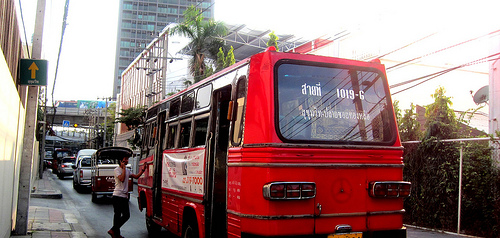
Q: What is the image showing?
A: It is showing a road.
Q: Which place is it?
A: It is a road.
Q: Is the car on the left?
A: Yes, the car is on the left of the image.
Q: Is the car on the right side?
A: No, the car is on the left of the image.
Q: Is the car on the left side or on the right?
A: The car is on the left of the image.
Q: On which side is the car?
A: The car is on the left of the image.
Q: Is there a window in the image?
A: Yes, there is a window.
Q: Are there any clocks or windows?
A: Yes, there is a window.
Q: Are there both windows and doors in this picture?
A: Yes, there are both a window and doors.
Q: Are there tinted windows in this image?
A: Yes, there is a tinted window.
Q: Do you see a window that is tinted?
A: Yes, there is a window that is tinted.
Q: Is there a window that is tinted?
A: Yes, there is a window that is tinted.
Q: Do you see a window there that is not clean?
A: Yes, there is a tinted window.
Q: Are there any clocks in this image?
A: No, there are no clocks.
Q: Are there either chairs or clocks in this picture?
A: No, there are no clocks or chairs.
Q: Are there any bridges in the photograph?
A: Yes, there is a bridge.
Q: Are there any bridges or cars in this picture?
A: Yes, there is a bridge.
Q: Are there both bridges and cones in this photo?
A: No, there is a bridge but no cones.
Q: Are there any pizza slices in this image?
A: No, there are no pizza slices.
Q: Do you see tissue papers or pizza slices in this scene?
A: No, there are no pizza slices or tissue papers.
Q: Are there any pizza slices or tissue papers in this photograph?
A: No, there are no pizza slices or tissue papers.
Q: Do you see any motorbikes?
A: No, there are no motorbikes.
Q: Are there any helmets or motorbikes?
A: No, there are no motorbikes or helmets.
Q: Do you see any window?
A: Yes, there is a window.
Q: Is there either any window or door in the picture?
A: Yes, there is a window.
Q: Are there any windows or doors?
A: Yes, there is a window.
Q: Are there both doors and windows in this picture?
A: Yes, there are both a window and a door.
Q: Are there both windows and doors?
A: Yes, there are both a window and a door.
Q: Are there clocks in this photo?
A: No, there are no clocks.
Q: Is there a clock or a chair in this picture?
A: No, there are no clocks or chairs.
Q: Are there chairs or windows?
A: Yes, there is a window.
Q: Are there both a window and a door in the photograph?
A: Yes, there are both a window and a door.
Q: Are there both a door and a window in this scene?
A: Yes, there are both a window and a door.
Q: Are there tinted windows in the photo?
A: Yes, there is a tinted window.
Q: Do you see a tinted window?
A: Yes, there is a tinted window.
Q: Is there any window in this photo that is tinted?
A: Yes, there is a window that is tinted.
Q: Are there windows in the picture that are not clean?
A: Yes, there is a tinted window.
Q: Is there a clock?
A: No, there are no clocks.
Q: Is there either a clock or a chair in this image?
A: No, there are no clocks or chairs.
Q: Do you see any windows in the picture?
A: Yes, there is a window.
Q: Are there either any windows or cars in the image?
A: Yes, there is a window.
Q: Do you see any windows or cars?
A: Yes, there is a window.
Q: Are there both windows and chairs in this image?
A: No, there is a window but no chairs.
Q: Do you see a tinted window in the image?
A: Yes, there is a tinted window.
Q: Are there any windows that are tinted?
A: Yes, there is a window that is tinted.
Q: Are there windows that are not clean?
A: Yes, there is a tinted window.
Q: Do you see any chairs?
A: No, there are no chairs.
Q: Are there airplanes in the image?
A: No, there are no airplanes.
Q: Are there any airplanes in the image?
A: No, there are no airplanes.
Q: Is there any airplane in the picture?
A: No, there are no airplanes.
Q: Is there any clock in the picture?
A: No, there are no clocks.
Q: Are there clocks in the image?
A: No, there are no clocks.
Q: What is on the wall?
A: The sign is on the wall.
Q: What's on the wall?
A: The sign is on the wall.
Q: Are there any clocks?
A: No, there are no clocks.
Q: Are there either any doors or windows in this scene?
A: Yes, there is a window.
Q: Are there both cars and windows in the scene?
A: Yes, there are both a window and a car.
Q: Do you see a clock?
A: No, there are no clocks.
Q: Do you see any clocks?
A: No, there are no clocks.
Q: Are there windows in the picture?
A: Yes, there is a window.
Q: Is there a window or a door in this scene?
A: Yes, there is a window.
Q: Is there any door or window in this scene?
A: Yes, there is a window.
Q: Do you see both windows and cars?
A: Yes, there are both a window and a car.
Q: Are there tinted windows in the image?
A: Yes, there is a tinted window.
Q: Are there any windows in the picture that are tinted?
A: Yes, there is a window that is tinted.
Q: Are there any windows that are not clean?
A: Yes, there is a tinted window.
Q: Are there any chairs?
A: No, there are no chairs.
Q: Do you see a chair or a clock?
A: No, there are no chairs or clocks.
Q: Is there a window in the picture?
A: Yes, there is a window.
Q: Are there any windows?
A: Yes, there is a window.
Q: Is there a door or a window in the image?
A: Yes, there is a window.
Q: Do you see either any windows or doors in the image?
A: Yes, there is a window.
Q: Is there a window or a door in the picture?
A: Yes, there is a window.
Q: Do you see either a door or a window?
A: Yes, there is a window.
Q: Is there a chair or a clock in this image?
A: No, there are no clocks or chairs.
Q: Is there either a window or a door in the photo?
A: Yes, there is a window.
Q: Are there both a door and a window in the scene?
A: Yes, there are both a window and a door.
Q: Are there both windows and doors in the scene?
A: Yes, there are both a window and a door.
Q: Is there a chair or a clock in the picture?
A: No, there are no clocks or chairs.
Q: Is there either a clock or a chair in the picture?
A: No, there are no clocks or chairs.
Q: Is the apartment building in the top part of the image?
A: Yes, the apartment building is in the top of the image.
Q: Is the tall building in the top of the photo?
A: Yes, the apartment building is in the top of the image.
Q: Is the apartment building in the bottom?
A: No, the apartment building is in the top of the image.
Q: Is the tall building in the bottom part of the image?
A: No, the apartment building is in the top of the image.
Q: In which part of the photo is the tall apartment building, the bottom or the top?
A: The apartment building is in the top of the image.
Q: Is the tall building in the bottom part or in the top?
A: The apartment building is in the top of the image.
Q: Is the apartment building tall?
A: Yes, the apartment building is tall.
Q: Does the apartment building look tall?
A: Yes, the apartment building is tall.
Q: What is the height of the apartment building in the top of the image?
A: The apartment building is tall.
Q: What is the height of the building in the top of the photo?
A: The apartment building is tall.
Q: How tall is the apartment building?
A: The apartment building is tall.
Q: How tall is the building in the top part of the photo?
A: The apartment building is tall.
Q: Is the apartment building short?
A: No, the apartment building is tall.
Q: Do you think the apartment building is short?
A: No, the apartment building is tall.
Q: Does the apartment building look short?
A: No, the apartment building is tall.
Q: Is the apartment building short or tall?
A: The apartment building is tall.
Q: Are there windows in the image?
A: Yes, there is a window.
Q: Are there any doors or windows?
A: Yes, there is a window.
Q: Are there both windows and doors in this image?
A: Yes, there are both a window and doors.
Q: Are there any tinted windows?
A: Yes, there is a tinted window.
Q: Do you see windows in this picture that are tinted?
A: Yes, there is a window that is tinted.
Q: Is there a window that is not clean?
A: Yes, there is a tinted window.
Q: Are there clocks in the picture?
A: No, there are no clocks.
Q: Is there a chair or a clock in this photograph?
A: No, there are no clocks or chairs.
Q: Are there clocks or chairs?
A: No, there are no clocks or chairs.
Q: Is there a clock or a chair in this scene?
A: No, there are no clocks or chairs.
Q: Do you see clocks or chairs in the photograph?
A: No, there are no clocks or chairs.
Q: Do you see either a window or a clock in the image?
A: Yes, there is a window.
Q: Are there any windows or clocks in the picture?
A: Yes, there is a window.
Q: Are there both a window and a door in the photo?
A: Yes, there are both a window and a door.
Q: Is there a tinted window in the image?
A: Yes, there is a tinted window.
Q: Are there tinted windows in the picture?
A: Yes, there is a tinted window.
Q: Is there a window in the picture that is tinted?
A: Yes, there is a window that is tinted.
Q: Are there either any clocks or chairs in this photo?
A: No, there are no clocks or chairs.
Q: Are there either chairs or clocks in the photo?
A: No, there are no clocks or chairs.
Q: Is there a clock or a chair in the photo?
A: No, there are no clocks or chairs.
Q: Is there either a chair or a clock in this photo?
A: No, there are no clocks or chairs.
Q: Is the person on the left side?
A: Yes, the person is on the left of the image.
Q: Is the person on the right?
A: No, the person is on the left of the image.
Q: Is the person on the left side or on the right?
A: The person is on the left of the image.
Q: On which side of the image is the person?
A: The person is on the left of the image.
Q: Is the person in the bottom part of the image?
A: Yes, the person is in the bottom of the image.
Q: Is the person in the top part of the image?
A: No, the person is in the bottom of the image.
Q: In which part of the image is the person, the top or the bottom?
A: The person is in the bottom of the image.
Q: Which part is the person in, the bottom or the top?
A: The person is in the bottom of the image.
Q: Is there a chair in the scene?
A: No, there are no chairs.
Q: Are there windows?
A: Yes, there is a window.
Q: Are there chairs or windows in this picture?
A: Yes, there is a window.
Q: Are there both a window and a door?
A: Yes, there are both a window and a door.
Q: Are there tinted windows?
A: Yes, there is a tinted window.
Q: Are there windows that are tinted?
A: Yes, there is a window that is tinted.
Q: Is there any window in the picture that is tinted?
A: Yes, there is a window that is tinted.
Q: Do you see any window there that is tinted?
A: Yes, there is a window that is tinted.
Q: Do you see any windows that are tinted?
A: Yes, there is a window that is tinted.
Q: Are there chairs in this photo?
A: No, there are no chairs.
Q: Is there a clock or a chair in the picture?
A: No, there are no chairs or clocks.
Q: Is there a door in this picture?
A: Yes, there is a door.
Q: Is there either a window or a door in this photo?
A: Yes, there is a door.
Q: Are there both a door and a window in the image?
A: Yes, there are both a door and a window.